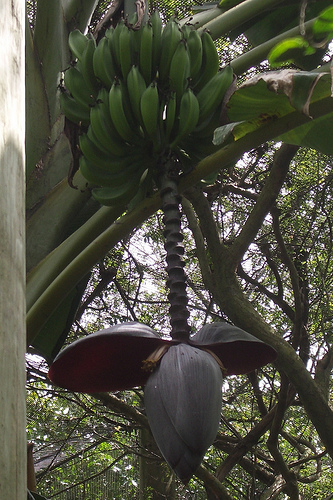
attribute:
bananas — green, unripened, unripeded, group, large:
[58, 10, 244, 202]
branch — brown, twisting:
[170, 164, 326, 353]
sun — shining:
[3, 3, 39, 158]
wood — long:
[185, 181, 333, 451]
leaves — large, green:
[216, 1, 331, 163]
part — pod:
[59, 164, 304, 469]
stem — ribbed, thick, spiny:
[150, 167, 209, 341]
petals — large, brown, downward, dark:
[40, 310, 284, 375]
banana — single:
[141, 77, 170, 155]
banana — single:
[106, 77, 137, 155]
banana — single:
[168, 40, 201, 101]